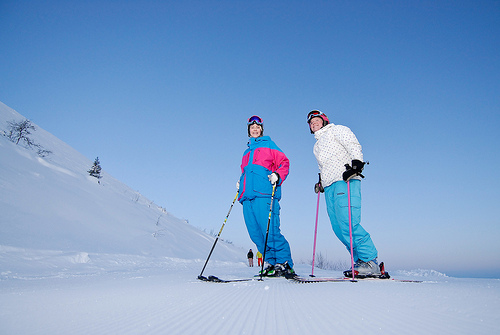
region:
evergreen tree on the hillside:
[89, 156, 101, 176]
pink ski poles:
[311, 183, 356, 277]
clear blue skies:
[0, 0, 490, 255]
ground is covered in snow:
[1, 104, 495, 334]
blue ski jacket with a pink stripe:
[238, 137, 288, 199]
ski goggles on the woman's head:
[305, 111, 327, 122]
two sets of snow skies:
[200, 270, 389, 282]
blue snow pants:
[321, 179, 377, 261]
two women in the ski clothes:
[203, 108, 423, 283]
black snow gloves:
[342, 159, 363, 180]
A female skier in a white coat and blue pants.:
[306, 108, 382, 279]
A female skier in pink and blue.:
[235, 114, 295, 279]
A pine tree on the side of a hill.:
[86, 155, 101, 179]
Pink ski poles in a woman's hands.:
[309, 170, 355, 281]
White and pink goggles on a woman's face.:
[304, 107, 330, 121]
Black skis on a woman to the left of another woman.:
[196, 272, 296, 282]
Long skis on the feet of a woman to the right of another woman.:
[288, 270, 424, 282]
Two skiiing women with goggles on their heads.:
[235, 108, 381, 275]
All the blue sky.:
[1, 1, 499, 267]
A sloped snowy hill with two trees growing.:
[0, 98, 250, 262]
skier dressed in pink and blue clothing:
[236, 114, 301, 279]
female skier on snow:
[238, 113, 300, 280]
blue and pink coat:
[236, 136, 293, 203]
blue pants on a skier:
[235, 197, 296, 260]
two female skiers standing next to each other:
[195, 106, 427, 288]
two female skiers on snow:
[196, 106, 427, 291]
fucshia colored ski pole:
[341, 175, 363, 282]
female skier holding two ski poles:
[303, 107, 395, 284]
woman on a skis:
[298, 106, 394, 283]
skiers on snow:
[196, 107, 394, 284]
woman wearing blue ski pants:
[242, 197, 309, 278]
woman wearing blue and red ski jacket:
[235, 143, 282, 211]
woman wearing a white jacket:
[307, 130, 372, 184]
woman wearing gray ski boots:
[340, 259, 385, 278]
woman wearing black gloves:
[343, 155, 370, 180]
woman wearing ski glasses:
[246, 113, 263, 126]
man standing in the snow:
[237, 241, 271, 270]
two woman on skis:
[212, 87, 391, 317]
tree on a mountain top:
[86, 153, 103, 185]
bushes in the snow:
[1, 108, 55, 164]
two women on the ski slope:
[195, 109, 426, 283]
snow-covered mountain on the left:
[3, 99, 256, 262]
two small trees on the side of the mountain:
[13, 118, 103, 179]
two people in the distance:
[245, 248, 264, 265]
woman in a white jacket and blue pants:
[308, 108, 388, 280]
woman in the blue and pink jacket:
[240, 112, 297, 279]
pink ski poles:
[309, 175, 355, 280]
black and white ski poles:
[200, 184, 276, 278]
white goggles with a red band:
[307, 109, 327, 131]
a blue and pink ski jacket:
[236, 138, 290, 199]